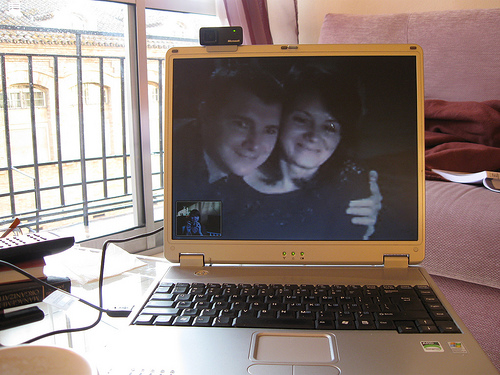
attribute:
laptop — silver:
[114, 42, 484, 367]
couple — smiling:
[177, 68, 415, 238]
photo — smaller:
[172, 199, 221, 237]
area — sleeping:
[427, 94, 479, 282]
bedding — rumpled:
[428, 98, 483, 163]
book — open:
[430, 164, 481, 184]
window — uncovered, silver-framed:
[4, 4, 209, 258]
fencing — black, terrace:
[6, 23, 186, 225]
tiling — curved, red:
[10, 10, 196, 30]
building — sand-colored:
[6, 9, 210, 209]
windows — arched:
[11, 77, 158, 173]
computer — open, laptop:
[101, 44, 484, 366]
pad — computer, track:
[250, 330, 338, 364]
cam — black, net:
[198, 24, 246, 45]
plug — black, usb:
[103, 303, 130, 315]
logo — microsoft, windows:
[446, 339, 466, 354]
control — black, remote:
[1, 223, 78, 267]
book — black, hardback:
[5, 277, 67, 311]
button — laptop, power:
[191, 266, 210, 279]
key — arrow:
[440, 322, 458, 335]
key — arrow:
[418, 323, 439, 333]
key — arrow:
[398, 321, 416, 332]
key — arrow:
[417, 315, 433, 323]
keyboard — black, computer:
[138, 273, 467, 336]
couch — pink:
[429, 178, 481, 272]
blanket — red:
[436, 128, 478, 168]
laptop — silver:
[125, 41, 456, 372]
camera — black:
[190, 14, 244, 46]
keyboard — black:
[148, 285, 458, 336]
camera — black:
[192, 27, 265, 51]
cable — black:
[40, 278, 143, 328]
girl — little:
[179, 206, 205, 238]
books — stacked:
[4, 257, 72, 310]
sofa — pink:
[423, 171, 498, 365]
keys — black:
[128, 279, 461, 340]